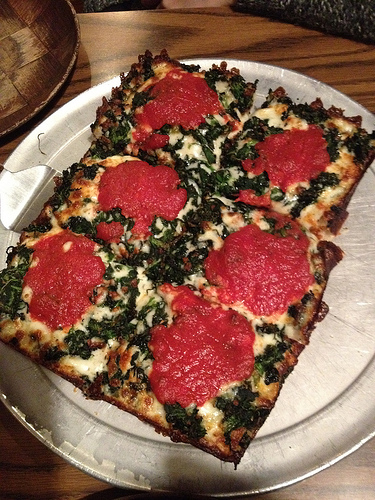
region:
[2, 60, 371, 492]
the plate is made of metal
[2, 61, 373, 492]
the plate is grey in color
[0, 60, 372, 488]
the plate is silver in color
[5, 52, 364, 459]
the pizza is square in shape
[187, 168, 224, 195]
spinach is on the pizza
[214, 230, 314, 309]
tomato sauce is on the pizza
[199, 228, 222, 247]
cheese is on the pizza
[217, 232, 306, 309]
the sauce is red in color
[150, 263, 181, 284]
the spinach is green in color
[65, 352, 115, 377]
the cheese is white in color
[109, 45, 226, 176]
a slice of pizza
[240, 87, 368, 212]
a slice of pizza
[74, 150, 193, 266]
a slice of pizza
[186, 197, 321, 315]
a slice of pizza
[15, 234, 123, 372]
a slice of pizza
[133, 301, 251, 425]
a slice of pizza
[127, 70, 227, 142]
tomato paste on a pizza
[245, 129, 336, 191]
tomato paste on a pizza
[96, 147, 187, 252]
tomato paste on a pizza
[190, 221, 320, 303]
tomato paste on a pizza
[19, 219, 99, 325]
the sauce is red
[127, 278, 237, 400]
the sauce is red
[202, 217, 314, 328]
the sauce is red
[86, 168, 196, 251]
the sauce is red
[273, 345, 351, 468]
the tray is gray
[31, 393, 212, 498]
the tray is gray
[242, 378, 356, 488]
the tray is gray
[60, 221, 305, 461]
This is square pizza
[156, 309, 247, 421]
The sauce is red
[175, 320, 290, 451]
This is red sauce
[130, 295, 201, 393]
The sauce is tomato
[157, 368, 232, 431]
This is crushed basil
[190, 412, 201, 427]
The basil is green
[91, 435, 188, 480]
This is a pizza pan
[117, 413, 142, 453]
The pan is silver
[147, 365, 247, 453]
This is a flat bread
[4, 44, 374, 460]
just baked rectangular pizza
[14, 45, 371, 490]
pizza on round silver baking pan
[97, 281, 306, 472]
square slice of pizza topped with glob of tomato sauce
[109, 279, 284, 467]
green spinach and browned cheese on pizza slice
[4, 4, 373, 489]
wooden table under pizza pan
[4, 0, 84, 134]
round empty wooden bowl on table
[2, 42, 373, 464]
pizza cut into 6 square slices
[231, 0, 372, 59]
person's arm in gray sweater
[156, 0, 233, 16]
white hand of person resting against table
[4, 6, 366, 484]
indoor restaurant daytime scene